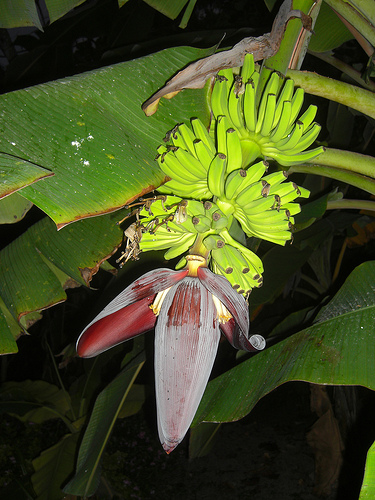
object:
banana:
[260, 93, 277, 138]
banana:
[206, 153, 229, 198]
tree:
[0, 1, 374, 499]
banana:
[210, 69, 227, 126]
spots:
[22, 117, 113, 169]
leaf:
[0, 48, 163, 221]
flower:
[73, 265, 270, 447]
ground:
[1, 425, 374, 499]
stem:
[144, 0, 321, 296]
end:
[239, 168, 247, 177]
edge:
[55, 173, 175, 231]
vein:
[293, 325, 371, 363]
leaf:
[199, 258, 373, 425]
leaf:
[142, 0, 309, 118]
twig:
[123, 189, 164, 207]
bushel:
[156, 115, 302, 248]